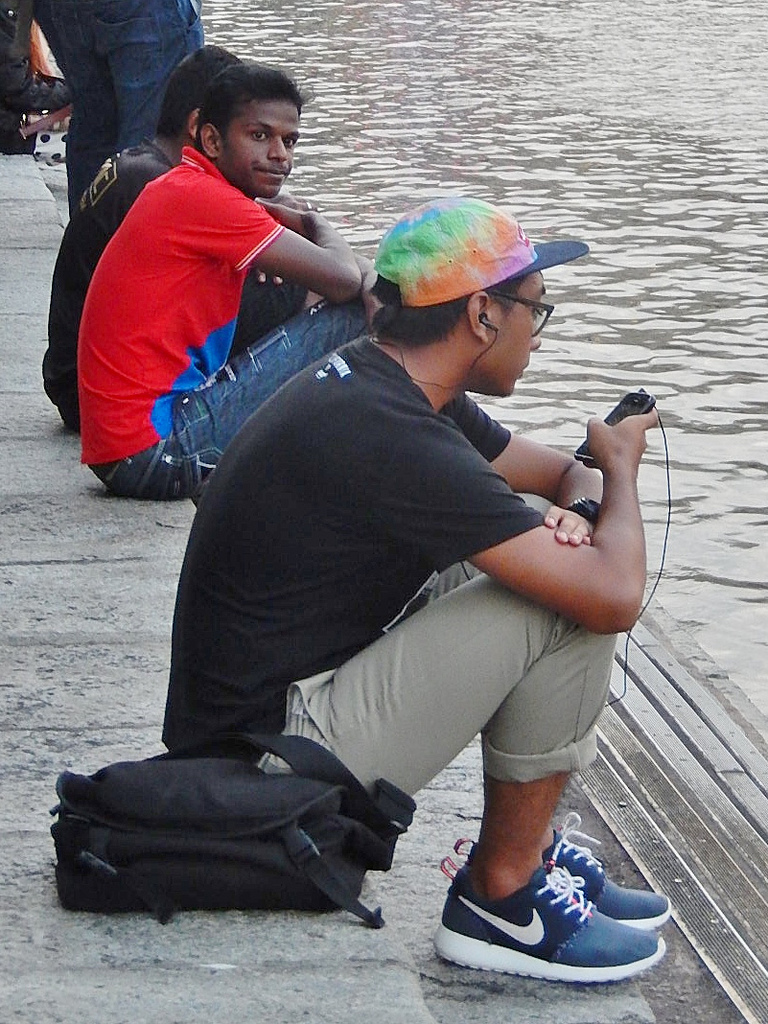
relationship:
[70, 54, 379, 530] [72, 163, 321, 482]
boy with shirt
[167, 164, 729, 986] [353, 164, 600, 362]
boy wearing a cap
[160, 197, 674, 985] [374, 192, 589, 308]
boy wearing cap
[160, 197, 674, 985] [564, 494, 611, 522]
boy wearing watch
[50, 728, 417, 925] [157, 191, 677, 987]
bag next to boy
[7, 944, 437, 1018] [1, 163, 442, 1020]
stone in floor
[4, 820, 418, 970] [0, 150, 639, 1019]
stone in floor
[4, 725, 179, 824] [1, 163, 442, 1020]
stone in floor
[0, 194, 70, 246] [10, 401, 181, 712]
stone in floor